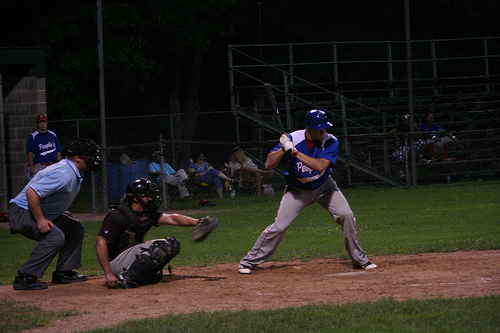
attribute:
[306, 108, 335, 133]
helmet — blue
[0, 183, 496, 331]
grass — green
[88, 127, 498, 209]
fence — large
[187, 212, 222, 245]
leather glove — black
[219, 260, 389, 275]
sneakers — black, white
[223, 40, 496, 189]
stands — metal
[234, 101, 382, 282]
man — holding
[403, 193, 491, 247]
green — brown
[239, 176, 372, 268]
pants — wrinkled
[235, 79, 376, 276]
batter — holding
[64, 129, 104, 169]
mask — face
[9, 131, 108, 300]
umpire — standing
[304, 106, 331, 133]
helmet — shiny, blue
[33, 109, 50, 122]
hat — red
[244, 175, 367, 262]
pants — grey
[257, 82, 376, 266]
batter — ready